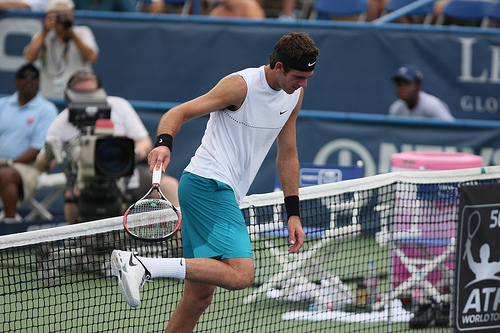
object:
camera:
[42, 101, 144, 223]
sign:
[457, 204, 499, 330]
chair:
[0, 171, 67, 224]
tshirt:
[183, 64, 300, 205]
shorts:
[178, 168, 253, 261]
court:
[6, 137, 423, 329]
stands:
[2, 5, 481, 238]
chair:
[242, 193, 363, 307]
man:
[35, 68, 184, 242]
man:
[0, 64, 58, 225]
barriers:
[1, 6, 481, 235]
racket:
[119, 164, 183, 242]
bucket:
[391, 152, 481, 321]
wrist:
[284, 196, 299, 214]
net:
[2, 171, 451, 332]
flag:
[452, 183, 500, 333]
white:
[201, 70, 306, 215]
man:
[106, 31, 321, 333]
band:
[284, 195, 301, 220]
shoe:
[111, 249, 147, 309]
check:
[128, 253, 137, 266]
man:
[19, 0, 100, 104]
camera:
[51, 14, 75, 34]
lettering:
[460, 285, 497, 325]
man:
[384, 57, 467, 123]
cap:
[390, 65, 424, 86]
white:
[387, 87, 454, 124]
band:
[270, 51, 318, 73]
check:
[308, 61, 316, 67]